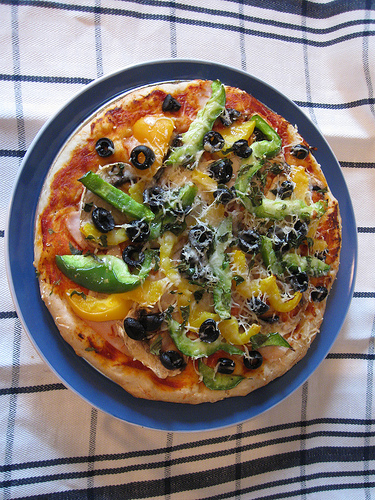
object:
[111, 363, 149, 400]
crust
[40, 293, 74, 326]
crust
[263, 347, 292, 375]
crust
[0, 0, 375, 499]
stripes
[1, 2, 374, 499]
tablecloth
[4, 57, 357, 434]
dish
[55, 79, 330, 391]
slice pepper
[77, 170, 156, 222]
pepper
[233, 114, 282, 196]
pepper slice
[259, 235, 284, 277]
pepper slice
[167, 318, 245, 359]
pepper slice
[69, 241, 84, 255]
fresh basil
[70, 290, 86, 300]
fresh basil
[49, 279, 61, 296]
fresh basil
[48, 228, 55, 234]
fresh basil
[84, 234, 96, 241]
fresh basil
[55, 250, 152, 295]
green pepper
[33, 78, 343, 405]
pizza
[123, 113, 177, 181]
pepper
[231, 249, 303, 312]
pepper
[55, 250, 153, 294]
pepper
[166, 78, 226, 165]
pepper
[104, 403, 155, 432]
edge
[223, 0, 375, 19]
lines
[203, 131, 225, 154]
olives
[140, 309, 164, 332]
olives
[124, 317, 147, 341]
olives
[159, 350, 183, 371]
olives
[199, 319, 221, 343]
olives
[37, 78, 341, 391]
sauce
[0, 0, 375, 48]
lines/tablecloth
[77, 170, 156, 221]
green pepper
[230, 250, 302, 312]
yellow pepper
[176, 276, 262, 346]
yellow pepper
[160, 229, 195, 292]
yellow pepper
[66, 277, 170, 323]
yellow pepper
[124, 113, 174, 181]
yellow pepper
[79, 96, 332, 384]
cheese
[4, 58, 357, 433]
exterior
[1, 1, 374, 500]
table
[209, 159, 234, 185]
olive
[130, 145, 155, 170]
anchovie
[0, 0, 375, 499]
cloth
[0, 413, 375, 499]
black line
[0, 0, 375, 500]
pattern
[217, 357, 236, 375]
olive